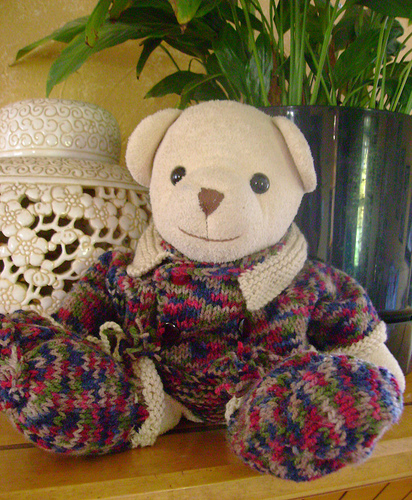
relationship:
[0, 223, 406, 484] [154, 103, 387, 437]
outfit on teddy bear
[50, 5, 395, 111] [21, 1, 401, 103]
stems on plants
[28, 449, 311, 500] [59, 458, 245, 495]
lines on table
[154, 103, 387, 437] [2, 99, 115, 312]
teddy bear beside vase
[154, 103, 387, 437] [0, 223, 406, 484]
teddy bear wears outfit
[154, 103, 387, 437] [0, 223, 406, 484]
teddy bear dressed in outfit